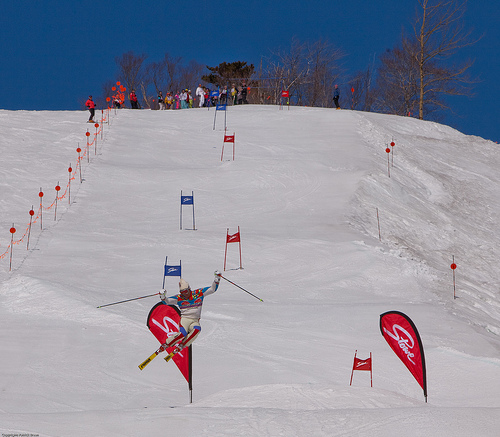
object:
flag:
[350, 354, 371, 371]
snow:
[0, 104, 499, 433]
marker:
[180, 194, 195, 206]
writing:
[321, 150, 356, 214]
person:
[155, 279, 220, 356]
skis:
[137, 335, 176, 371]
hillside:
[0, 194, 499, 351]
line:
[0, 100, 120, 285]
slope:
[0, 117, 362, 368]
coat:
[127, 93, 138, 101]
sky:
[0, 0, 499, 143]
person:
[330, 84, 344, 110]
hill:
[0, 104, 499, 265]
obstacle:
[222, 223, 243, 271]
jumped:
[137, 268, 222, 371]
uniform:
[159, 278, 221, 347]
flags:
[163, 262, 182, 277]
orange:
[109, 80, 127, 91]